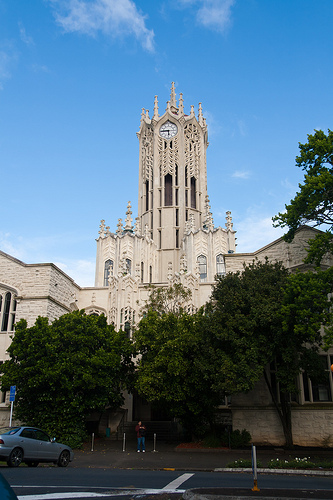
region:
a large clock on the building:
[158, 118, 178, 140]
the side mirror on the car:
[49, 435, 58, 443]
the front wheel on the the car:
[58, 448, 72, 466]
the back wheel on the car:
[10, 443, 26, 468]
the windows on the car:
[20, 426, 50, 439]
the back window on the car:
[1, 423, 20, 434]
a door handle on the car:
[37, 441, 46, 447]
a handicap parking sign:
[6, 383, 22, 408]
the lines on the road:
[161, 466, 196, 495]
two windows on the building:
[194, 251, 227, 278]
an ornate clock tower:
[133, 76, 215, 231]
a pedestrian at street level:
[132, 418, 148, 454]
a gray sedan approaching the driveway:
[1, 423, 175, 470]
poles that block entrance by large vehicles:
[86, 429, 160, 454]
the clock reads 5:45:
[156, 116, 181, 142]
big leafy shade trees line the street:
[132, 260, 331, 452]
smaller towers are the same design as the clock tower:
[89, 196, 242, 282]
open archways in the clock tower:
[137, 167, 205, 216]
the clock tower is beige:
[132, 77, 214, 235]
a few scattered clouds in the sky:
[10, 2, 313, 77]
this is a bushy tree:
[4, 301, 135, 451]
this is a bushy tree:
[221, 277, 288, 462]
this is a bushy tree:
[143, 353, 190, 398]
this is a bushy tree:
[135, 274, 243, 434]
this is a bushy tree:
[134, 337, 190, 413]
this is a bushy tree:
[48, 368, 90, 406]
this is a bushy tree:
[58, 318, 112, 365]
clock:
[160, 118, 180, 148]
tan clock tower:
[131, 85, 212, 231]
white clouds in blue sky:
[14, 21, 36, 64]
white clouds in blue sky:
[50, 37, 78, 69]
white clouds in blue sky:
[42, 88, 67, 131]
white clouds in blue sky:
[75, 158, 109, 202]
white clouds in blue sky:
[22, 172, 54, 216]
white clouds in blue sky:
[240, 29, 284, 73]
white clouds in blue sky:
[242, 99, 264, 138]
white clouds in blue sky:
[151, 17, 224, 80]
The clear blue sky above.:
[0, 88, 122, 215]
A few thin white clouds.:
[0, 0, 249, 69]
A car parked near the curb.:
[0, 417, 75, 468]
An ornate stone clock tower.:
[85, 81, 237, 264]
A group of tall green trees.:
[21, 260, 330, 425]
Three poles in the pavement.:
[86, 434, 161, 451]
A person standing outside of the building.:
[133, 418, 144, 455]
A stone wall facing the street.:
[228, 404, 331, 450]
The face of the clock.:
[160, 122, 180, 138]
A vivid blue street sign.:
[5, 385, 15, 403]